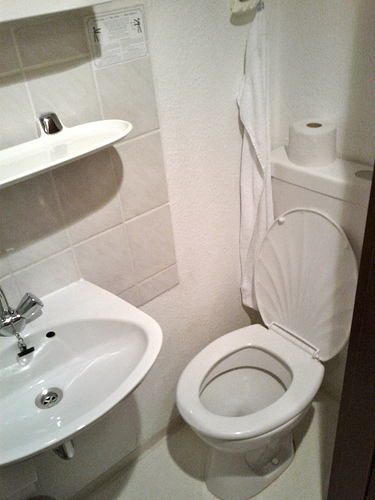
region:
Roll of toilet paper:
[286, 119, 342, 166]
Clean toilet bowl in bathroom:
[179, 329, 322, 447]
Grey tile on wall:
[122, 220, 179, 284]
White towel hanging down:
[226, 14, 275, 310]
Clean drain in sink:
[35, 386, 65, 409]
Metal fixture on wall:
[39, 112, 66, 138]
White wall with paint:
[167, 23, 232, 105]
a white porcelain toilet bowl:
[175, 325, 316, 497]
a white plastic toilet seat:
[175, 323, 325, 439]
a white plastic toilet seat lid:
[252, 204, 358, 363]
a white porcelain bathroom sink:
[0, 279, 164, 464]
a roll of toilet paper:
[289, 116, 336, 167]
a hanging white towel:
[234, 9, 273, 312]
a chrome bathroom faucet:
[0, 282, 43, 336]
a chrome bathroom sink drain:
[33, 383, 60, 407]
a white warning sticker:
[83, 5, 149, 68]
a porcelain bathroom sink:
[0, 275, 163, 464]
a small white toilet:
[176, 150, 368, 497]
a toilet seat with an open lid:
[175, 211, 359, 440]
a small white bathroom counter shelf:
[0, 107, 151, 187]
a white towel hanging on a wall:
[235, 30, 278, 319]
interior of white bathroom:
[1, 1, 373, 498]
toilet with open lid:
[174, 207, 357, 498]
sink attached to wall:
[0, 277, 162, 465]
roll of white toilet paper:
[286, 117, 335, 164]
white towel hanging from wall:
[234, 3, 276, 309]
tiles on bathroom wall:
[2, 5, 178, 306]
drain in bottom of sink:
[34, 387, 60, 408]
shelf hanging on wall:
[0, 110, 132, 186]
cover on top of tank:
[266, 144, 368, 260]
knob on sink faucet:
[1, 284, 42, 334]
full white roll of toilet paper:
[285, 118, 339, 169]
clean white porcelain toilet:
[174, 144, 373, 498]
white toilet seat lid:
[251, 208, 358, 364]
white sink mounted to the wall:
[0, 279, 162, 476]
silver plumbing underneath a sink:
[50, 435, 78, 460]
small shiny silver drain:
[32, 384, 62, 409]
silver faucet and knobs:
[1, 286, 44, 341]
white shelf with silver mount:
[0, 110, 131, 191]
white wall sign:
[81, 2, 147, 71]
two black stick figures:
[89, 15, 142, 42]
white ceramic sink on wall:
[0, 276, 166, 474]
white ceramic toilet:
[171, 139, 371, 497]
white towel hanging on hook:
[230, 3, 283, 314]